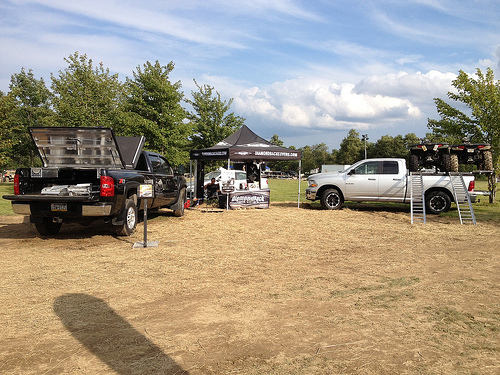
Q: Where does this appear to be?
A: Park.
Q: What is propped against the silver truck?
A: Ladders.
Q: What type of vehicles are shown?
A: Trucks.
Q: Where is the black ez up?
A: Between the 2 trucks.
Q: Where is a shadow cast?
A: On the ground.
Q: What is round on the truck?
A: Tires.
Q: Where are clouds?
A: In the sky.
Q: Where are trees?
A: In the distance.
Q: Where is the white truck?
A: On the right.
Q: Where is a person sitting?
A: Under a tent.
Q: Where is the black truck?
A: On the left.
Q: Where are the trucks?
A: On a field.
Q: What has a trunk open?
A: Truck on the left.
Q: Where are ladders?
A: Next to the white truck.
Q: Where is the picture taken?
A: A park.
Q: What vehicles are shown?
A: Trucks.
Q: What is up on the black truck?
A: Bed cover.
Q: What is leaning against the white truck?
A: Ladders.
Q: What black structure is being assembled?
A: A tent.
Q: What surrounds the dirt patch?
A: Trees.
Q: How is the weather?
A: Sunny.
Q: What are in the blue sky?
A: Clouds.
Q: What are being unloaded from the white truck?
A: Off road vehicles.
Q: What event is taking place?
A: An off road competition.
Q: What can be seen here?
A: Trucks.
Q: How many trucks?
A: Two.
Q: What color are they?
A: One black, one gray.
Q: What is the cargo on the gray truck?
A: ATVs.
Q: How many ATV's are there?
A: Two.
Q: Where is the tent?
A: In the middle of the trucks.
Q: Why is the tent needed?
A: To block sun.